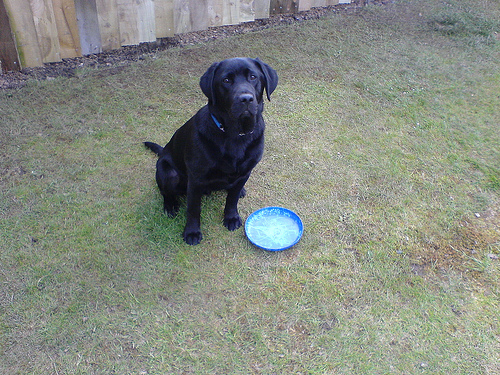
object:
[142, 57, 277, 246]
dog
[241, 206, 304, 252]
frisbee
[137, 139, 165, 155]
tail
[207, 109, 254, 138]
collar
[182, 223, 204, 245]
paw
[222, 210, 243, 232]
paw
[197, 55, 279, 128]
head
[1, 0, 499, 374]
yard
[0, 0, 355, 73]
fence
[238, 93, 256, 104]
nose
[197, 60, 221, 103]
ear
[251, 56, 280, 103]
ear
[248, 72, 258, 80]
eye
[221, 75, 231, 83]
eye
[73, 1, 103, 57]
wood plank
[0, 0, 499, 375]
fluffy grass